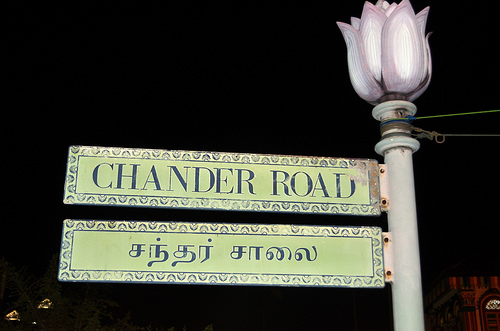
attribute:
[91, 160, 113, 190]
letter — C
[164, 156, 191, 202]
n — blue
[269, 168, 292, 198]
r — Blue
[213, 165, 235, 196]
e — Blue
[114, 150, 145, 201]
letter — blue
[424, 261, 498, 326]
building — small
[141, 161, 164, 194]
letter — A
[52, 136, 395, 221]
sign — street, for Chander Road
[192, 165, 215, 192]
letter — blue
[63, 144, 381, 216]
street sign — green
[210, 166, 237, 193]
e — letter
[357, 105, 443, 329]
pole — metal 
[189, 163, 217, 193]
d — blue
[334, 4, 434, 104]
top — flower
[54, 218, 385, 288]
sign — street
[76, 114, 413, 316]
sign — street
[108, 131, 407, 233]
sign — street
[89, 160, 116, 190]
letter — blue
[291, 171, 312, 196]
o — letter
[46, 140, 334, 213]
sign — street, green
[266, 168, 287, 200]
letter — R 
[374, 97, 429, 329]
post — metal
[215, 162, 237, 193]
letter — blue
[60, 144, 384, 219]
sign — green, street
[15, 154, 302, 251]
sign — blue, street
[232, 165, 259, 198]
letter — blue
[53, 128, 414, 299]
street sign — green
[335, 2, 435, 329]
post — lamp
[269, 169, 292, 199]
letter — blue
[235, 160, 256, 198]
r — letter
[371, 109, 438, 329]
pole — metal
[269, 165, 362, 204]
road — blue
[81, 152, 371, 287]
sign — green, street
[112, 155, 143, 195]
letter — blue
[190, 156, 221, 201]
letter — blue, green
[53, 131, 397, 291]
sign — green, street